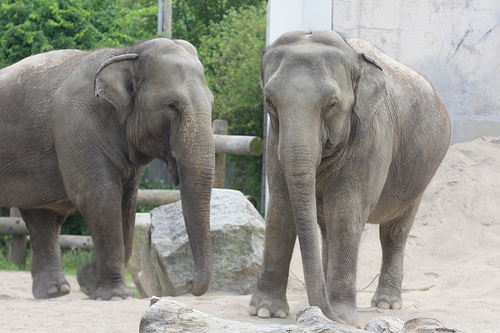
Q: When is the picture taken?
A: Daytime.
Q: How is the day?
A: Sunny.